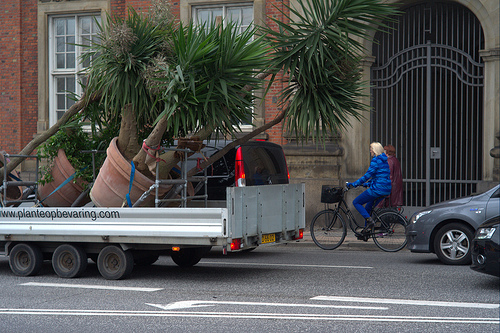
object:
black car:
[469, 216, 499, 277]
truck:
[0, 182, 307, 281]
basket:
[320, 184, 344, 204]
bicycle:
[309, 181, 410, 252]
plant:
[175, 53, 377, 182]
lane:
[2, 243, 498, 333]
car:
[404, 183, 500, 266]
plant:
[0, 65, 122, 186]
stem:
[323, 84, 361, 118]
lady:
[347, 142, 393, 234]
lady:
[375, 143, 405, 236]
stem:
[212, 77, 229, 103]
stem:
[104, 52, 142, 95]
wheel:
[96, 245, 135, 280]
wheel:
[51, 243, 88, 279]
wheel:
[8, 242, 43, 276]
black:
[484, 245, 500, 262]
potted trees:
[88, 0, 406, 206]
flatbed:
[0, 199, 230, 248]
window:
[190, 2, 256, 134]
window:
[45, 8, 109, 132]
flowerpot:
[89, 136, 174, 209]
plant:
[130, 19, 235, 170]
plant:
[78, 20, 175, 161]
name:
[0, 208, 121, 220]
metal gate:
[366, 0, 484, 215]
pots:
[35, 147, 93, 207]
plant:
[150, 0, 403, 180]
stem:
[196, 47, 234, 92]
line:
[18, 281, 165, 293]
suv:
[148, 135, 291, 255]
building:
[2, 0, 498, 228]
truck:
[2, 135, 318, 296]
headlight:
[472, 228, 495, 239]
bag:
[321, 186, 344, 203]